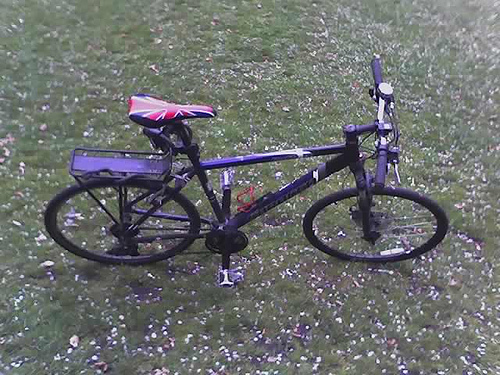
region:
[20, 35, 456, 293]
bike on the lawn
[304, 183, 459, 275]
front tire on bike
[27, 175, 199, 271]
rear tire on bike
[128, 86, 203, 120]
flag pattern on seat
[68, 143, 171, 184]
shelf on the bike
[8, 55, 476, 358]
lawn bike is on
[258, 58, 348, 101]
plant debris on ground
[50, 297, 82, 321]
green patch of grass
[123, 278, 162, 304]
dirt patch with few grass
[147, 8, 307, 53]
brown and green grass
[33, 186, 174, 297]
the wheel on a bike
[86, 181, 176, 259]
the spokes on a bike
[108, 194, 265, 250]
a chain on a bike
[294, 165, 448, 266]
the front wheel on a bike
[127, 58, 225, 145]
a seat on a bike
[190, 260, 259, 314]
a paddle on a bike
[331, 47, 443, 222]
the handlebars on a bike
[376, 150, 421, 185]
the brakes on a bike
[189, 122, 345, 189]
the middle bar on a bike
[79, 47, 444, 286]
a bike on the grass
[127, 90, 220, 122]
british flag on seat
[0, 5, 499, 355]
green grass under bike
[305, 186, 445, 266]
rubber tire on bike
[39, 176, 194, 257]
rubber tire on bike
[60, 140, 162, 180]
basket holder on bike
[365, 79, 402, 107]
small guage on handle bars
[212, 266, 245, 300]
metal pedal on bike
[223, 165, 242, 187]
metal pedal on bike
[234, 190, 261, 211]
water bottle holder on bike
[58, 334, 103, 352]
small pebbles in grass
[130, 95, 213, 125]
THIS SEAT HAS A UNION JACK DESIGN ON IT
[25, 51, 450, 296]
THIS IS A BICYCLE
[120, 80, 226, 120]
THIS IS A BIKE SEAT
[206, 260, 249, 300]
THIS IS A BIKE PEDDAL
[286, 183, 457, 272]
THIS TIRE HAS MANY SPOKES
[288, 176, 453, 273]
THIS IS A BIKE TIRE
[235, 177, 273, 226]
THIS IS A BOTTLE HOLDER ON A BIKE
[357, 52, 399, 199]
THESE ARE HANDLEBARS ON A BIKE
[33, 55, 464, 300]
THE BIKE IS PARKED IN THE GRASS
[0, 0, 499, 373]
a small grassy field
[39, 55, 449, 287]
a small purple bicycle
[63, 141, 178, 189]
a holder on a bike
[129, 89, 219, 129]
a union jack seat on a bike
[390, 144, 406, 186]
the brake handle of a bike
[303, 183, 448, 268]
a bicycle tire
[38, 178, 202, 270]
a bicycle tire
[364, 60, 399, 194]
the handlebars of a bike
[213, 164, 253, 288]
the pedals of a bike